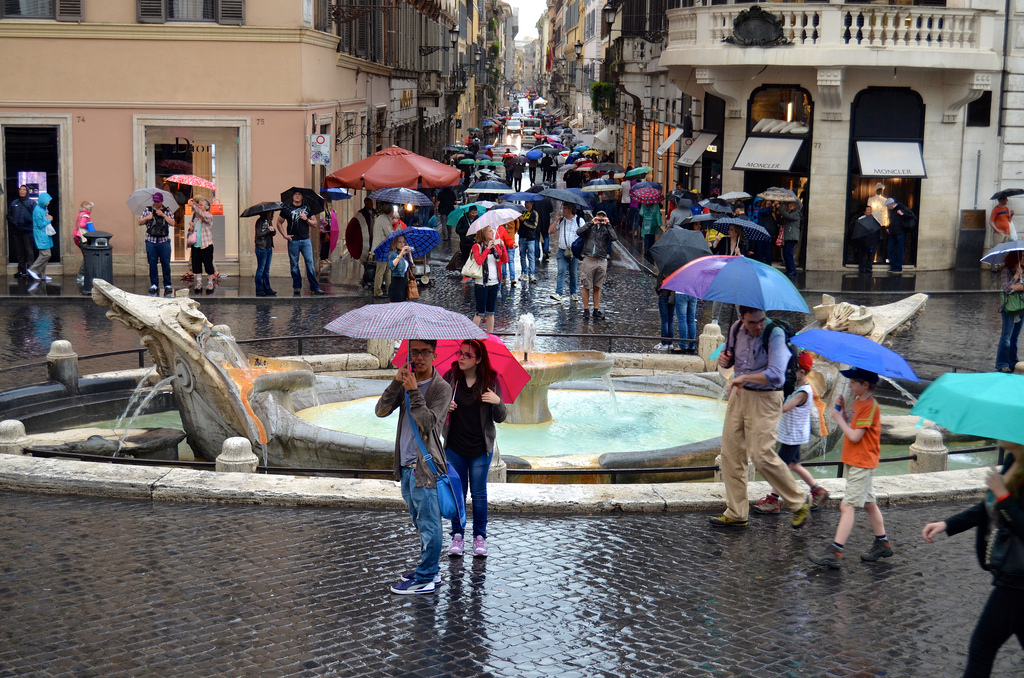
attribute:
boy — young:
[810, 365, 904, 580]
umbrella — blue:
[776, 324, 932, 396]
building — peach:
[13, 5, 474, 301]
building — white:
[533, 1, 1018, 302]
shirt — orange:
[834, 368, 887, 475]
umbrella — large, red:
[322, 130, 469, 191]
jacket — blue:
[30, 180, 59, 261]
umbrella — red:
[384, 325, 532, 401]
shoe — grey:
[390, 558, 449, 608]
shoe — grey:
[380, 552, 445, 604]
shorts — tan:
[840, 461, 892, 516]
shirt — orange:
[836, 396, 888, 463]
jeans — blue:
[380, 446, 465, 555]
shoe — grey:
[375, 560, 464, 615]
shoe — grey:
[382, 565, 450, 598]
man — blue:
[362, 320, 492, 602]